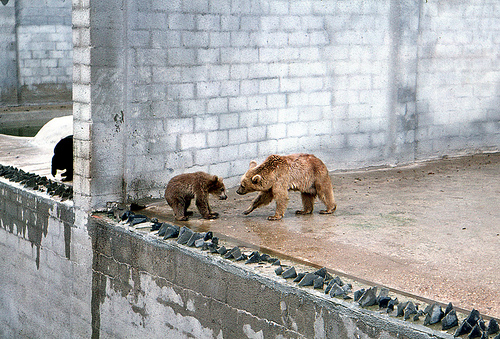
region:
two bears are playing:
[142, 134, 362, 249]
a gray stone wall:
[102, 19, 401, 156]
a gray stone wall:
[75, 0, 293, 144]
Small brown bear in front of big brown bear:
[163, 171, 228, 219]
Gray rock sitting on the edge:
[274, 263, 286, 274]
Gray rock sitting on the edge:
[280, 265, 296, 280]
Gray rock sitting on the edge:
[328, 281, 343, 294]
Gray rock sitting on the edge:
[162, 224, 178, 239]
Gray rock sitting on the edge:
[439, 307, 459, 327]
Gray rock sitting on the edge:
[452, 318, 470, 335]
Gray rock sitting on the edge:
[487, 315, 499, 332]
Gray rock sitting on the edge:
[386, 294, 398, 309]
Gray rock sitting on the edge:
[312, 275, 324, 290]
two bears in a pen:
[158, 137, 348, 229]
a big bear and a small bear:
[155, 144, 345, 231]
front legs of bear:
[238, 189, 288, 223]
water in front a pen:
[78, 148, 359, 315]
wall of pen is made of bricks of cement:
[70, 8, 499, 200]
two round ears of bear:
[245, 155, 266, 188]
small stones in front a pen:
[112, 208, 495, 335]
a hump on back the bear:
[256, 145, 290, 169]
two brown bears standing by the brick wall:
[161, 155, 343, 220]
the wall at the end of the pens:
[2, 182, 420, 337]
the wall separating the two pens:
[78, 5, 495, 198]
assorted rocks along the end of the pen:
[116, 205, 498, 337]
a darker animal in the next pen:
[43, 137, 76, 182]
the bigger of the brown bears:
[233, 153, 337, 220]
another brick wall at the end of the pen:
[3, 3, 70, 103]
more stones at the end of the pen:
[2, 164, 73, 205]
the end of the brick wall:
[70, 0, 87, 336]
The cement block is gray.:
[131, 8, 168, 33]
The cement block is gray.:
[165, 10, 197, 35]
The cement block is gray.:
[193, 13, 222, 33]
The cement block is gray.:
[148, 27, 185, 52]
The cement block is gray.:
[177, 27, 212, 52]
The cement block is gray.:
[203, 28, 235, 51]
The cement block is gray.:
[133, 46, 171, 67]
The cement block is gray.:
[166, 45, 199, 68]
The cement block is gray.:
[146, 63, 185, 85]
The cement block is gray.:
[178, 61, 212, 84]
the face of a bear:
[225, 169, 256, 202]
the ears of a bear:
[240, 160, 266, 186]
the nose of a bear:
[233, 180, 243, 197]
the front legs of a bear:
[240, 184, 290, 234]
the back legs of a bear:
[292, 186, 335, 226]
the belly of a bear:
[284, 168, 316, 196]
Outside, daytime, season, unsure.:
[2, 8, 498, 337]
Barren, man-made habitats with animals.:
[4, 0, 499, 333]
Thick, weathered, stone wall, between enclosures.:
[75, 11, 362, 123]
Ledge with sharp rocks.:
[117, 201, 295, 274]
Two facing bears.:
[153, 149, 350, 227]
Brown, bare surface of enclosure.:
[370, 183, 466, 270]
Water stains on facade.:
[93, 233, 251, 337]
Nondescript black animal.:
[39, 126, 78, 195]